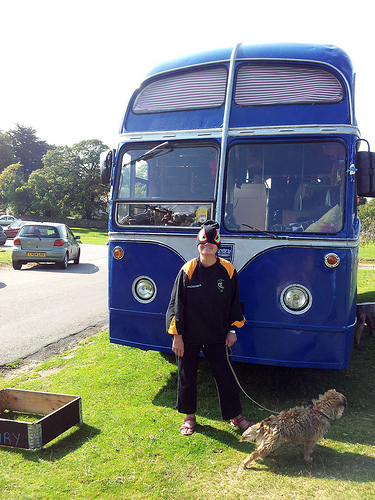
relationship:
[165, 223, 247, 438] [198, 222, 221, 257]
person wearing costume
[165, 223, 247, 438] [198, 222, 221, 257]
person wearing mask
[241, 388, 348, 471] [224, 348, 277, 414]
dog on leash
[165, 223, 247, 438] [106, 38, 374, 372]
person next to bus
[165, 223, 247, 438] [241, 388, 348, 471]
person with dog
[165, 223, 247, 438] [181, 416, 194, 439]
person wearing sandal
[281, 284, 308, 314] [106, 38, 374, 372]
light on bus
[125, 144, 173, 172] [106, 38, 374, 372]
wiper on bus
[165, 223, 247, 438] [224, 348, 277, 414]
person holding leash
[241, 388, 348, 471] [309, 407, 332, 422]
dog wearing collar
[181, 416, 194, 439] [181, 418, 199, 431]
sandal has straps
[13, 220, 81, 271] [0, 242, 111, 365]
car driving on street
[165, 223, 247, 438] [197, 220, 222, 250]
person wearing hat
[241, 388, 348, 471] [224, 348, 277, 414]
dog has leash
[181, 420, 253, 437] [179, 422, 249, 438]
sandles on feet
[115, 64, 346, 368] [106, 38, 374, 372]
front of bus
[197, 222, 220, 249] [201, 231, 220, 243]
hat has eyes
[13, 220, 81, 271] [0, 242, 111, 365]
car on street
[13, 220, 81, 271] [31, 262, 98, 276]
car has shadow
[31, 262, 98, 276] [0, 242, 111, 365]
shadow on street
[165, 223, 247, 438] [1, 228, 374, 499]
person in grass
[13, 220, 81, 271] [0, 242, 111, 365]
car in street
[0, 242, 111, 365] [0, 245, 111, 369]
street has pavement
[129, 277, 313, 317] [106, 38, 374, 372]
lights on front of bus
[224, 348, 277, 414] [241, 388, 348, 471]
leash holding dog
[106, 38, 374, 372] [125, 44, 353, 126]
bus has sleeper cab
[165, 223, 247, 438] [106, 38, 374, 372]
person in front of bus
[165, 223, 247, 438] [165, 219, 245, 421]
person wearing costume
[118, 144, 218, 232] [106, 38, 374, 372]
window on front of bus